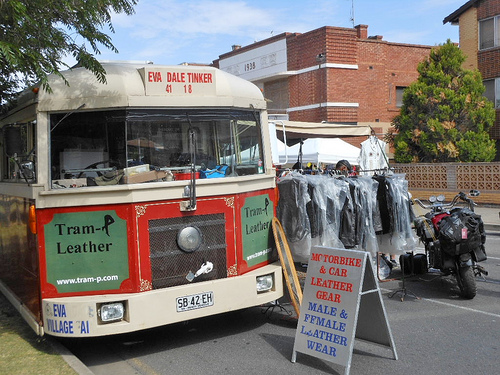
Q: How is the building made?
A: Out of red bricks.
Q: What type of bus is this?
A: An older bus.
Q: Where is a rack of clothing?
A: Besides of bus.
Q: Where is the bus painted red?
A: A section in the front.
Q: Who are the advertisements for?
A: Tram leather.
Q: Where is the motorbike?
A: Parked on the street.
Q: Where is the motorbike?
A: Parked beside clothing.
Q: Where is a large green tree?
A: Beside the red building.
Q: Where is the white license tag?
A: On bumper of the bus.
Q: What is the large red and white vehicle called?
A: Bus.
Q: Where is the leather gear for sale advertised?
A: White sign on street.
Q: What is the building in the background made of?
A: Brick.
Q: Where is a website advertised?
A: Front of bus.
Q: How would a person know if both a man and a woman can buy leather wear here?
A: Sign.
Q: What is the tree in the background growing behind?
A: A wall.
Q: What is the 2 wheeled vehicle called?
A: Motorcycle.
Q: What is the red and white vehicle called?
A: Bus.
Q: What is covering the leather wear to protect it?
A: Plastic.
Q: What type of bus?
A: Very old.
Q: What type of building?
A: Large and brick.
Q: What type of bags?
A: Plastic and protective.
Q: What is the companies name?
A: Tram Leather.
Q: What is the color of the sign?
A: White.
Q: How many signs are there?
A: One.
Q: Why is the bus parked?
A: To do business.